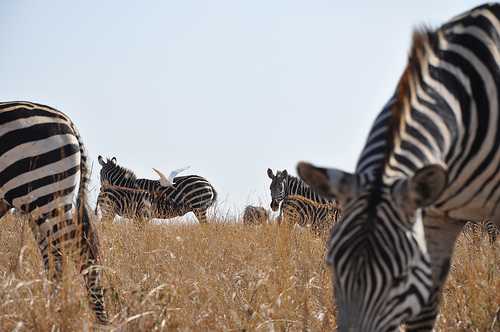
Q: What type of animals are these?
A: Zebras.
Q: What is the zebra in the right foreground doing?
A: Grazing.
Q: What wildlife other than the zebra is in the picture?
A: Bird.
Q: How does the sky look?
A: Clear.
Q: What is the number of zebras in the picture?
A: 7.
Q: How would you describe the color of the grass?
A: Brown.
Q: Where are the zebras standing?
A: In a field.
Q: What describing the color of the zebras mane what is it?
A: Brown.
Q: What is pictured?
A: Animals.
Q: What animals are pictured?
A: A bird and zebras.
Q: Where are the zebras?
A: In a field.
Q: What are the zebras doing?
A: Eating.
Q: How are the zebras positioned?
A: Standing.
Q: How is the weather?
A: Clear.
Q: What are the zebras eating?
A: Grass.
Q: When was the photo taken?
A: During day hours.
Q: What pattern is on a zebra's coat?
A: Black and white stripes.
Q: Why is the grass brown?
A: Dry.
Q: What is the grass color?
A: Brown.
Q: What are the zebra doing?
A: Grazing.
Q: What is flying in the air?
A: Bird.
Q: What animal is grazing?
A: Zebra.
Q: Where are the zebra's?
A: Field.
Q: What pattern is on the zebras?
A: Stripes.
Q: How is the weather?
A: Sunny.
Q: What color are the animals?
A: Black and white.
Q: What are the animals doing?
A: Eating.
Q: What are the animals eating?
A: Grass.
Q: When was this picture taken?
A: Daytime.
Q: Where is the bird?
A: By the zebra.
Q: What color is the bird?
A: White.